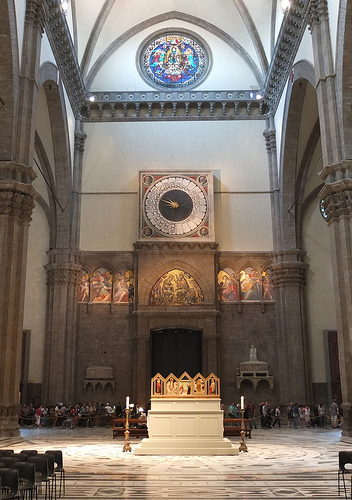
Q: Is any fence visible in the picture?
A: No, there are no fences.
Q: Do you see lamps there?
A: No, there are no lamps.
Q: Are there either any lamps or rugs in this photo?
A: No, there are no lamps or rugs.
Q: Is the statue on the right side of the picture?
A: Yes, the statue is on the right of the image.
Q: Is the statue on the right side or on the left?
A: The statue is on the right of the image.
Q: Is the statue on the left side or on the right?
A: The statue is on the right of the image.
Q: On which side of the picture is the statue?
A: The statue is on the right of the image.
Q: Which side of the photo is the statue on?
A: The statue is on the right of the image.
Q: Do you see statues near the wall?
A: Yes, there is a statue near the wall.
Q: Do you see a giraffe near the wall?
A: No, there is a statue near the wall.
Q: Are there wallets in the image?
A: No, there are no wallets.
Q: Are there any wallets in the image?
A: No, there are no wallets.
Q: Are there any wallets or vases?
A: No, there are no wallets or vases.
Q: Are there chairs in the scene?
A: Yes, there is a chair.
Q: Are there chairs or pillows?
A: Yes, there is a chair.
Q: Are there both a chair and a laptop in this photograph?
A: No, there is a chair but no laptops.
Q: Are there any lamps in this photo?
A: No, there are no lamps.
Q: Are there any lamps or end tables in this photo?
A: No, there are no lamps or end tables.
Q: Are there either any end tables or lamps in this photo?
A: No, there are no lamps or end tables.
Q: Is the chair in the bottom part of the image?
A: Yes, the chair is in the bottom of the image.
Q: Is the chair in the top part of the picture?
A: No, the chair is in the bottom of the image.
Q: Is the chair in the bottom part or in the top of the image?
A: The chair is in the bottom of the image.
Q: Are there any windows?
A: Yes, there is a window.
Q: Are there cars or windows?
A: Yes, there is a window.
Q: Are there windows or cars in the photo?
A: Yes, there is a window.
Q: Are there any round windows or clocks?
A: Yes, there is a round window.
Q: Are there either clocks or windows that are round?
A: Yes, the window is round.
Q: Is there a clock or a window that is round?
A: Yes, the window is round.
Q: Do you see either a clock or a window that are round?
A: Yes, the window is round.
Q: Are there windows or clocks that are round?
A: Yes, the window is round.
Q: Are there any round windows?
A: Yes, there is a round window.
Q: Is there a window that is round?
A: Yes, there is a window that is round.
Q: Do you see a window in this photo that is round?
A: Yes, there is a window that is round.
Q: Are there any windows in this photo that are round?
A: Yes, there is a window that is round.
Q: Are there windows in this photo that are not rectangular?
A: Yes, there is a round window.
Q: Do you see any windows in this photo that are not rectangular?
A: Yes, there is a round window.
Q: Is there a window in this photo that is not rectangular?
A: Yes, there is a round window.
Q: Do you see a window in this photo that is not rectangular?
A: Yes, there is a round window.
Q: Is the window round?
A: Yes, the window is round.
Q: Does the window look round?
A: Yes, the window is round.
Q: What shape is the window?
A: The window is round.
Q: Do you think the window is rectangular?
A: No, the window is round.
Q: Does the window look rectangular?
A: No, the window is round.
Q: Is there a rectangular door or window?
A: No, there is a window but it is round.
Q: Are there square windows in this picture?
A: No, there is a window but it is round.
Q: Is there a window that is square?
A: No, there is a window but it is round.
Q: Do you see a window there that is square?
A: No, there is a window but it is round.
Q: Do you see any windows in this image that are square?
A: No, there is a window but it is round.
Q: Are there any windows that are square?
A: No, there is a window but it is round.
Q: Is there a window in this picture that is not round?
A: No, there is a window but it is round.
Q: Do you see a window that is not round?
A: No, there is a window but it is round.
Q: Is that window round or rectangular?
A: The window is round.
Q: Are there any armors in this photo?
A: No, there are no armors.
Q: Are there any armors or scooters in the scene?
A: No, there are no armors or scooters.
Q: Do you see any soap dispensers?
A: No, there are no soap dispensers.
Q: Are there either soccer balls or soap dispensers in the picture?
A: No, there are no soap dispensers or soccer balls.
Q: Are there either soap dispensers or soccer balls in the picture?
A: No, there are no soap dispensers or soccer balls.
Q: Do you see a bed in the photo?
A: No, there are no beds.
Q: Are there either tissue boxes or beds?
A: No, there are no beds or tissue boxes.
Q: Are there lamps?
A: No, there are no lamps.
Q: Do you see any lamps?
A: No, there are no lamps.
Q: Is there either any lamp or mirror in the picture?
A: No, there are no lamps or mirrors.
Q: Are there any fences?
A: No, there are no fences.